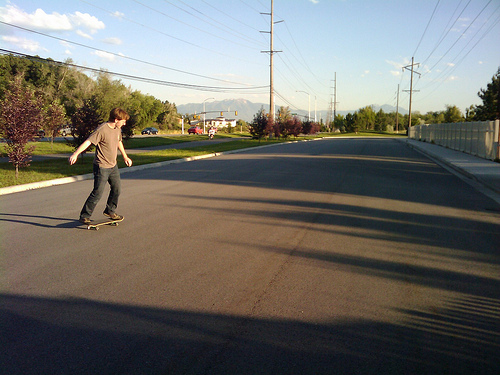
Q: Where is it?
A: This is at the street.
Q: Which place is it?
A: It is a street.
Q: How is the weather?
A: It is cloudy.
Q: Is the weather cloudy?
A: Yes, it is cloudy.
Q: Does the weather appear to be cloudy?
A: Yes, it is cloudy.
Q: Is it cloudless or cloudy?
A: It is cloudy.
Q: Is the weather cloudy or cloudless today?
A: It is cloudy.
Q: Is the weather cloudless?
A: No, it is cloudy.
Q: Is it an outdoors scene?
A: Yes, it is outdoors.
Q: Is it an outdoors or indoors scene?
A: It is outdoors.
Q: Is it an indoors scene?
A: No, it is outdoors.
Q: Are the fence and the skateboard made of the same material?
A: Yes, both the fence and the skateboard are made of wood.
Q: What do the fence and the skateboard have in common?
A: The material, both the fence and the skateboard are wooden.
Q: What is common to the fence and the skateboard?
A: The material, both the fence and the skateboard are wooden.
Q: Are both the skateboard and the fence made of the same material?
A: Yes, both the skateboard and the fence are made of wood.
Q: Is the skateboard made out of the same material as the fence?
A: Yes, both the skateboard and the fence are made of wood.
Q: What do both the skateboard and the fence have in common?
A: The material, both the skateboard and the fence are wooden.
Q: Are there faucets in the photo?
A: No, there are no faucets.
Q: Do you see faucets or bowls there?
A: No, there are no faucets or bowls.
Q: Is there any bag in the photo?
A: No, there are no bags.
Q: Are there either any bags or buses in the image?
A: No, there are no bags or buses.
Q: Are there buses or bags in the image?
A: No, there are no bags or buses.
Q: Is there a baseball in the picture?
A: No, there are no baseballs.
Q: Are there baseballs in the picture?
A: No, there are no baseballs.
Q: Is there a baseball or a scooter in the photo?
A: No, there are no baseballs or scooters.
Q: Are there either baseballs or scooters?
A: No, there are no baseballs or scooters.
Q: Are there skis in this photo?
A: No, there are no skis.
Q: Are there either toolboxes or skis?
A: No, there are no skis or toolboxes.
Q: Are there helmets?
A: No, there are no helmets.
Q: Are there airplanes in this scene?
A: No, there are no airplanes.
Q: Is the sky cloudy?
A: Yes, the sky is cloudy.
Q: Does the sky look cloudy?
A: Yes, the sky is cloudy.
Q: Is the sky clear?
A: No, the sky is cloudy.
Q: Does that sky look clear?
A: No, the sky is cloudy.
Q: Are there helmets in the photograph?
A: No, there are no helmets.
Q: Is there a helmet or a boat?
A: No, there are no helmets or boats.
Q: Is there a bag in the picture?
A: No, there are no bags.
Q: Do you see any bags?
A: No, there are no bags.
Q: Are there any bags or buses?
A: No, there are no bags or buses.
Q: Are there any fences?
A: Yes, there is a fence.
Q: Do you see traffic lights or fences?
A: Yes, there is a fence.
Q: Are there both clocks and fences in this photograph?
A: No, there is a fence but no clocks.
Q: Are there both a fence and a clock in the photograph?
A: No, there is a fence but no clocks.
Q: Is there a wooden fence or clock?
A: Yes, there is a wood fence.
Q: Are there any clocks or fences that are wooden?
A: Yes, the fence is wooden.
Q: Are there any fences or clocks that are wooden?
A: Yes, the fence is wooden.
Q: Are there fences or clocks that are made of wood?
A: Yes, the fence is made of wood.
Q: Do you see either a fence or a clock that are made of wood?
A: Yes, the fence is made of wood.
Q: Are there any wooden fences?
A: Yes, there is a wood fence.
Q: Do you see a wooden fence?
A: Yes, there is a wood fence.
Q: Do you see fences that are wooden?
A: Yes, there is a fence that is wooden.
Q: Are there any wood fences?
A: Yes, there is a fence that is made of wood.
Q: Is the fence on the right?
A: Yes, the fence is on the right of the image.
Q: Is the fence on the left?
A: No, the fence is on the right of the image.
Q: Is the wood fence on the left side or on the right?
A: The fence is on the right of the image.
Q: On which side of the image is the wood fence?
A: The fence is on the right of the image.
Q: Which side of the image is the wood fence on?
A: The fence is on the right of the image.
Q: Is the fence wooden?
A: Yes, the fence is wooden.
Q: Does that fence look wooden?
A: Yes, the fence is wooden.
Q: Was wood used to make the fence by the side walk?
A: Yes, the fence is made of wood.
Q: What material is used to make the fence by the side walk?
A: The fence is made of wood.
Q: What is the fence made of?
A: The fence is made of wood.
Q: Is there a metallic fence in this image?
A: No, there is a fence but it is wooden.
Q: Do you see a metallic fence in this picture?
A: No, there is a fence but it is wooden.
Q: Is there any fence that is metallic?
A: No, there is a fence but it is wooden.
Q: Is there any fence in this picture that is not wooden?
A: No, there is a fence but it is wooden.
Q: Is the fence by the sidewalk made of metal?
A: No, the fence is made of wood.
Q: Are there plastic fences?
A: No, there is a fence but it is made of wood.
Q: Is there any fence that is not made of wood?
A: No, there is a fence but it is made of wood.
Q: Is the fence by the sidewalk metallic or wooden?
A: The fence is wooden.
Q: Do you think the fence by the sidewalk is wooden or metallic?
A: The fence is wooden.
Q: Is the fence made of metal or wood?
A: The fence is made of wood.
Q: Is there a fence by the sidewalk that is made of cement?
A: Yes, there is a fence by the side walk.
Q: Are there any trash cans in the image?
A: No, there are no trash cans.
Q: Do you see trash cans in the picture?
A: No, there are no trash cans.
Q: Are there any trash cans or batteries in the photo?
A: No, there are no trash cans or batteries.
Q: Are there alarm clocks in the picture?
A: No, there are no alarm clocks.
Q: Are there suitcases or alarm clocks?
A: No, there are no alarm clocks or suitcases.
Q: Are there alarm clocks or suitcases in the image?
A: No, there are no alarm clocks or suitcases.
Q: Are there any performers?
A: No, there are no performers.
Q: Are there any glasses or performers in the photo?
A: No, there are no performers or glasses.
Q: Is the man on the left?
A: Yes, the man is on the left of the image.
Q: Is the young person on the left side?
A: Yes, the man is on the left of the image.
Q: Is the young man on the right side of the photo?
A: No, the man is on the left of the image.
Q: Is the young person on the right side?
A: No, the man is on the left of the image.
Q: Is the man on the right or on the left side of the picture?
A: The man is on the left of the image.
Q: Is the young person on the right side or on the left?
A: The man is on the left of the image.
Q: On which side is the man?
A: The man is on the left of the image.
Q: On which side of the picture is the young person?
A: The man is on the left of the image.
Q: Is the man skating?
A: Yes, the man is skating.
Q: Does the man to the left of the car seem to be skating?
A: Yes, the man is skating.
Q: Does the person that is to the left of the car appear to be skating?
A: Yes, the man is skating.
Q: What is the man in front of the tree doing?
A: The man is skating.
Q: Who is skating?
A: The man is skating.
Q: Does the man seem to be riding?
A: No, the man is skating.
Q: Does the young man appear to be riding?
A: No, the man is skating.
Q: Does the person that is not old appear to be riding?
A: No, the man is skating.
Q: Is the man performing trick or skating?
A: The man is skating.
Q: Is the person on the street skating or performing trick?
A: The man is skating.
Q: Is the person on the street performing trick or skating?
A: The man is skating.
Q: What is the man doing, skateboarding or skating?
A: The man is skating.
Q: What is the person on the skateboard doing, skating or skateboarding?
A: The man is skating.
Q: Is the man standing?
A: Yes, the man is standing.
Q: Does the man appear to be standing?
A: Yes, the man is standing.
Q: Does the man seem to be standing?
A: Yes, the man is standing.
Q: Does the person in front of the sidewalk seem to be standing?
A: Yes, the man is standing.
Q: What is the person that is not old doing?
A: The man is standing.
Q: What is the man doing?
A: The man is standing.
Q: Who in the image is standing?
A: The man is standing.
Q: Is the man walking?
A: No, the man is standing.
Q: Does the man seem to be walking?
A: No, the man is standing.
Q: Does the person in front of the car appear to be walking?
A: No, the man is standing.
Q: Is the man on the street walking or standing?
A: The man is standing.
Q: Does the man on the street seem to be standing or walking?
A: The man is standing.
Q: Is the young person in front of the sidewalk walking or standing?
A: The man is standing.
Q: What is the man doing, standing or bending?
A: The man is standing.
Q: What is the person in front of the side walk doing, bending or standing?
A: The man is standing.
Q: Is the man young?
A: Yes, the man is young.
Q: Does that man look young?
A: Yes, the man is young.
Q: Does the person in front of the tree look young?
A: Yes, the man is young.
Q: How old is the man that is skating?
A: The man is young.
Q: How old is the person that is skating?
A: The man is young.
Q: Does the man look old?
A: No, the man is young.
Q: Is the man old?
A: No, the man is young.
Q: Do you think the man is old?
A: No, the man is young.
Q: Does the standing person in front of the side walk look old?
A: No, the man is young.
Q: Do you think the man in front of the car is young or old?
A: The man is young.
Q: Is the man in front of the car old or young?
A: The man is young.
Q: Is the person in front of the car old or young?
A: The man is young.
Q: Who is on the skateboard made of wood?
A: The man is on the skateboard.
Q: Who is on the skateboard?
A: The man is on the skateboard.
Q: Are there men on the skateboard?
A: Yes, there is a man on the skateboard.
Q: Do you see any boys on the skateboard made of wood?
A: No, there is a man on the skateboard.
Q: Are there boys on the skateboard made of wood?
A: No, there is a man on the skateboard.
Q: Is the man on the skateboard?
A: Yes, the man is on the skateboard.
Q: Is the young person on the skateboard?
A: Yes, the man is on the skateboard.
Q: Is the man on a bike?
A: No, the man is on the skateboard.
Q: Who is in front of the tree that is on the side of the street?
A: The man is in front of the tree.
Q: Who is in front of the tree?
A: The man is in front of the tree.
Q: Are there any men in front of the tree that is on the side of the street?
A: Yes, there is a man in front of the tree.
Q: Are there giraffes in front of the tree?
A: No, there is a man in front of the tree.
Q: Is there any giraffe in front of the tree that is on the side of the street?
A: No, there is a man in front of the tree.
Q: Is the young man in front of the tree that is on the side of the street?
A: Yes, the man is in front of the tree.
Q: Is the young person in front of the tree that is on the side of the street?
A: Yes, the man is in front of the tree.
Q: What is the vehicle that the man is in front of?
A: The vehicle is a car.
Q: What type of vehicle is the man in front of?
A: The man is in front of the car.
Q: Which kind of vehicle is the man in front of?
A: The man is in front of the car.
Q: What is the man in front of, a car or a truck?
A: The man is in front of a car.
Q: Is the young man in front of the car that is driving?
A: Yes, the man is in front of the car.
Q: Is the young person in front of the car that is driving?
A: Yes, the man is in front of the car.